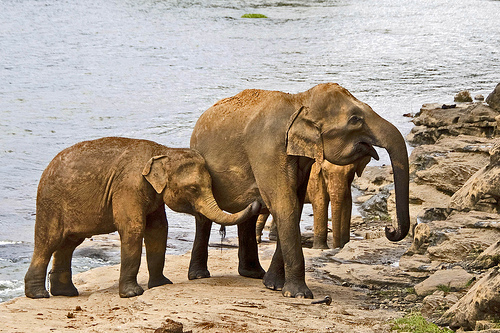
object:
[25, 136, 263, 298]
elephants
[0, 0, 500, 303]
water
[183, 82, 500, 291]
rocks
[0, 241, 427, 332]
sand